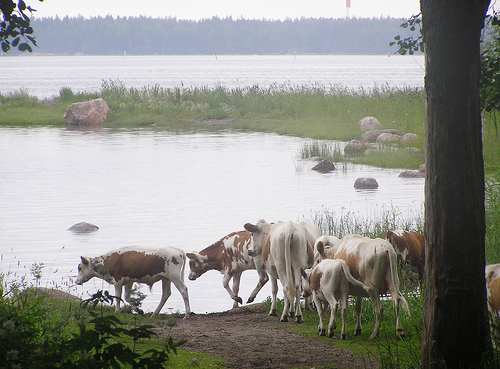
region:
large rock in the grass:
[63, 97, 112, 129]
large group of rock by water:
[310, 113, 424, 188]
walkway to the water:
[168, 300, 376, 365]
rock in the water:
[66, 220, 97, 233]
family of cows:
[72, 220, 494, 336]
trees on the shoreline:
[0, 12, 498, 54]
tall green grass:
[1, 76, 431, 127]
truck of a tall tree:
[420, 0, 496, 366]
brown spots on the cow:
[93, 246, 166, 281]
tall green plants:
[2, 267, 184, 367]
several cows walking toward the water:
[41, 157, 468, 367]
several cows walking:
[55, 206, 442, 363]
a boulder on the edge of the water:
[62, 92, 197, 209]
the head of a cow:
[65, 250, 95, 281]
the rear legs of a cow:
[150, 280, 190, 320]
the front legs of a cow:
[105, 271, 141, 311]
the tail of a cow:
[380, 241, 400, 306]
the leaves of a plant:
[68, 320, 139, 365]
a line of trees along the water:
[2, 6, 420, 67]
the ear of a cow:
[239, 217, 258, 236]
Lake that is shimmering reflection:
[100, 140, 215, 218]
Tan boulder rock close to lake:
[64, 94, 112, 128]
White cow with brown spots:
[69, 243, 198, 320]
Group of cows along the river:
[63, 217, 430, 367]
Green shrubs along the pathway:
[79, 301, 154, 364]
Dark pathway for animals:
[213, 315, 303, 362]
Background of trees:
[96, 12, 274, 52]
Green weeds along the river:
[249, 81, 340, 129]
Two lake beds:
[74, 48, 225, 202]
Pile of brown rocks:
[341, 108, 421, 169]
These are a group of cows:
[58, 230, 398, 312]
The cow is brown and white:
[83, 240, 181, 308]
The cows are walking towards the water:
[58, 213, 409, 340]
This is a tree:
[431, 121, 498, 241]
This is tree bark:
[419, 175, 485, 328]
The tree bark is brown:
[430, 170, 473, 250]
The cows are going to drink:
[63, 218, 399, 344]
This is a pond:
[27, 139, 267, 221]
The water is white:
[28, 141, 229, 222]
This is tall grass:
[153, 75, 372, 124]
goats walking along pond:
[61, 224, 412, 331]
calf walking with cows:
[294, 259, 348, 326]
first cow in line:
[83, 244, 194, 314]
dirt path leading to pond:
[161, 314, 314, 368]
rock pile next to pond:
[328, 111, 425, 160]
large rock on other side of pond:
[60, 92, 107, 125]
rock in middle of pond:
[65, 217, 97, 232]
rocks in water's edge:
[305, 152, 421, 194]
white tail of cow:
[283, 228, 302, 300]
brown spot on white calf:
[305, 269, 330, 294]